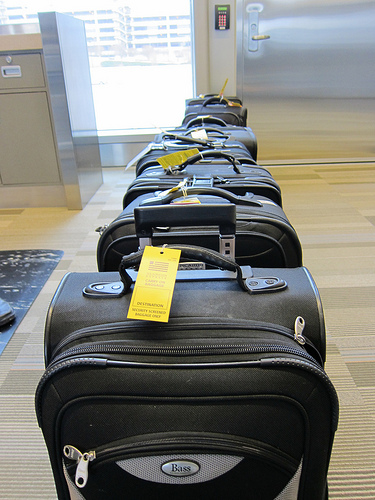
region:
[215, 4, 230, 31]
Security number keypad by door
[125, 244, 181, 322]
Yellow tag on carry-on suitcase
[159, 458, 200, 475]
Bass written on suitcase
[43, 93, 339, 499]
Row of eight black carry-on suitcases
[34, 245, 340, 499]
Black roller suitcase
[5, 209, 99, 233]
Beige carpet tile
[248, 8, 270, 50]
Heavy duty metal lock and handle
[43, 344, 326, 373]
Black zipper on suitcase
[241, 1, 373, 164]
Stainless steel heavy duty door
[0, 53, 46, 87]
Beige metal drawer with lock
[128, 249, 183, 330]
a yellow tag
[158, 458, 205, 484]
a label that says Bass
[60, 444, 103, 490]
two metallic zippers next to eachother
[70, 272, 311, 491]
a grey and black suit case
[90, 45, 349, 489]
a row of suitcases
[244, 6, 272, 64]
a copper colored door handle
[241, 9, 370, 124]
a metallic colored door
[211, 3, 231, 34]
a digital keypad with a green screen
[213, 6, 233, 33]
a key pad with red buttons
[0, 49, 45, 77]
a draw with a lock on it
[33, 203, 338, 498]
a black Bass luggage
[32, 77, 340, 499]
luggages on the floor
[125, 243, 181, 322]
a yellow tag on a black luggage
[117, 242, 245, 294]
a black hand held handle on a luggage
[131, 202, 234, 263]
a handle to pull the luggage on wheels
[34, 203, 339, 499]
a Bass luggage with zipper compartments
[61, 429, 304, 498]
a zipper compartment on the front of a luggage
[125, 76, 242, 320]
tags attached to the top of luggages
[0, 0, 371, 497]
luggages in an airport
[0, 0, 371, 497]
luggages on the floor at an airport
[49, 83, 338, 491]
There are lots of suitcases.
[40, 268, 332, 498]
The suitcase is black.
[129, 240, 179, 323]
The tag is yellow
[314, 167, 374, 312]
The floor is wood.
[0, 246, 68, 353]
The mat is black.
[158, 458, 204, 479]
The brand is Bass.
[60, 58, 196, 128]
The window is open.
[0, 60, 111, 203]
The cabinet is shut.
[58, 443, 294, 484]
The zipper is shut.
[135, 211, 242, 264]
The handle is up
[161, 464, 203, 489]
Label on front suitcase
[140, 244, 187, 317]
Tag on front suitcase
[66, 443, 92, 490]
Zippers on front suitcase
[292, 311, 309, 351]
Right zipper on suitcase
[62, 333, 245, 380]
Black zipper on suitcase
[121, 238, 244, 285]
Handle on front suitcase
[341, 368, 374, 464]
Brown carpet in the background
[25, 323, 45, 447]
Brown carpet at the left.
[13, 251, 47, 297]
Black table in the background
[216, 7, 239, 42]
Black button pad in the background